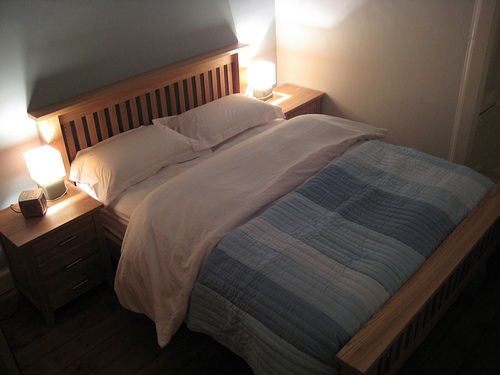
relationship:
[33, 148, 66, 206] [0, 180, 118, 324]
lamp on endtable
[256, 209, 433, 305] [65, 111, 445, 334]
blanket on bed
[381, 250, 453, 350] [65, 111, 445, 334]
footboard end of bed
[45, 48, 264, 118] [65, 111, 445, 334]
headboard front of bed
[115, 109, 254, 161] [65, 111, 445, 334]
pillows on bed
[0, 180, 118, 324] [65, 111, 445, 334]
endtable side of bed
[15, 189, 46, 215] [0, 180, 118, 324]
clock on endtable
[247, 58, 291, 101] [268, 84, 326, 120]
lamp on desk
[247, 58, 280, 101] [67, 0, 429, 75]
lamp on wall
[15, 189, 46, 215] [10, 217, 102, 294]
clock on endtable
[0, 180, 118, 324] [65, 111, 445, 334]
endtable near bed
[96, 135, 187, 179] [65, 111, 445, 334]
pillow on bed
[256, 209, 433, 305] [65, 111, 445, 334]
blanket on top of bed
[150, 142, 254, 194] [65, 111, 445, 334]
sheet on bed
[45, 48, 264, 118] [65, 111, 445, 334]
headboard of bed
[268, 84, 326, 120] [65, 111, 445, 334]
desk near bed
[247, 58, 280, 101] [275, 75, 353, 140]
lamp on desk